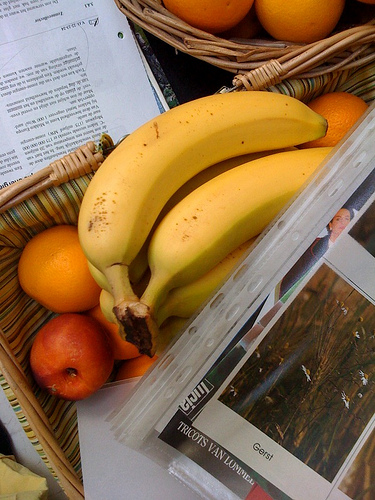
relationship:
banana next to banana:
[78, 88, 329, 317] [139, 146, 336, 311]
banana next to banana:
[139, 146, 336, 311] [150, 236, 259, 328]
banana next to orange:
[78, 88, 329, 317] [300, 89, 369, 149]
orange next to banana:
[300, 89, 369, 149] [78, 88, 329, 317]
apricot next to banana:
[19, 225, 102, 313] [78, 88, 329, 317]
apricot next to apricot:
[28, 313, 116, 402] [19, 225, 102, 313]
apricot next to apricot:
[19, 225, 102, 313] [28, 313, 116, 402]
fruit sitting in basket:
[14, 88, 363, 400] [0, 26, 374, 499]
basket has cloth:
[0, 26, 374, 499] [0, 68, 375, 491]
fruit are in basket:
[164, 1, 342, 42] [114, 1, 374, 75]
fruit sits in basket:
[14, 88, 363, 400] [0, 26, 374, 499]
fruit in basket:
[162, 1, 342, 41] [114, 1, 374, 75]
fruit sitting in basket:
[162, 1, 342, 41] [114, 1, 374, 75]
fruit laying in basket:
[14, 88, 363, 400] [0, 26, 374, 499]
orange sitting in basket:
[300, 89, 369, 149] [0, 26, 374, 499]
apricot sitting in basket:
[28, 313, 116, 402] [0, 26, 374, 499]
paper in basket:
[157, 167, 373, 499] [0, 26, 374, 499]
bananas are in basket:
[76, 88, 336, 359] [0, 26, 374, 499]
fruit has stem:
[14, 88, 363, 400] [103, 270, 172, 359]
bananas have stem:
[76, 88, 336, 359] [103, 270, 172, 359]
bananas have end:
[76, 88, 336, 359] [318, 114, 328, 139]